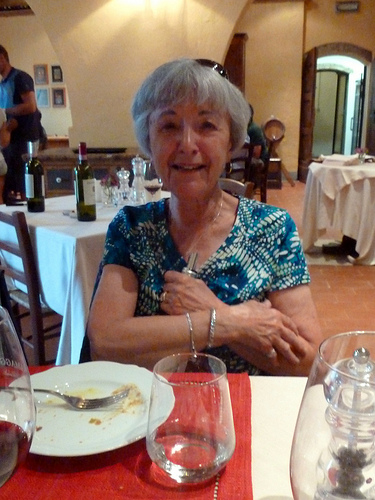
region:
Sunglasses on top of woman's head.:
[172, 42, 253, 104]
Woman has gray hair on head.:
[145, 68, 243, 132]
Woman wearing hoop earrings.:
[222, 149, 242, 183]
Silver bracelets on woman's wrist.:
[177, 306, 238, 374]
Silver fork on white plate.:
[55, 376, 131, 422]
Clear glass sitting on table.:
[157, 369, 220, 494]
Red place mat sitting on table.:
[94, 407, 243, 498]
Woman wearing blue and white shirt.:
[221, 265, 267, 301]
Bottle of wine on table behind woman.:
[59, 129, 104, 218]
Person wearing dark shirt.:
[5, 69, 60, 144]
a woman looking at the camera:
[80, 56, 320, 375]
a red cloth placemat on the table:
[41, 473, 135, 494]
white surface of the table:
[256, 409, 278, 441]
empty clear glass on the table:
[141, 356, 237, 481]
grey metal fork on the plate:
[9, 376, 126, 406]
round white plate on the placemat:
[4, 360, 156, 470]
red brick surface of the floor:
[317, 268, 358, 305]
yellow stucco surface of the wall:
[91, 36, 139, 57]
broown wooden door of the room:
[300, 50, 316, 177]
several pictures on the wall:
[31, 58, 68, 108]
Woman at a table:
[82, 61, 332, 385]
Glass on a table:
[141, 351, 254, 490]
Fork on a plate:
[10, 374, 133, 422]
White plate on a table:
[4, 362, 184, 453]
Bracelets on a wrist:
[177, 309, 226, 354]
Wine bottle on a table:
[68, 139, 101, 219]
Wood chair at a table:
[3, 196, 64, 359]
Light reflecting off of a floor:
[306, 263, 371, 325]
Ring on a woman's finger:
[157, 286, 172, 310]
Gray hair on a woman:
[133, 84, 249, 130]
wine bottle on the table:
[73, 141, 100, 220]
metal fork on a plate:
[2, 387, 127, 408]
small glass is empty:
[145, 355, 233, 484]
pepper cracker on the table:
[319, 346, 374, 498]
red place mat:
[2, 366, 251, 497]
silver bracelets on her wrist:
[185, 306, 216, 356]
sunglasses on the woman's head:
[164, 58, 228, 82]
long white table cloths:
[303, 158, 374, 259]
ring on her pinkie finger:
[268, 346, 274, 357]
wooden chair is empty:
[0, 211, 61, 364]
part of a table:
[327, 172, 328, 187]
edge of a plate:
[111, 450, 122, 458]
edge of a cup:
[163, 403, 175, 416]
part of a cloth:
[238, 481, 243, 487]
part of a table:
[283, 407, 296, 423]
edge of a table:
[262, 414, 280, 440]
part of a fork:
[89, 399, 97, 402]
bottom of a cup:
[182, 468, 190, 484]